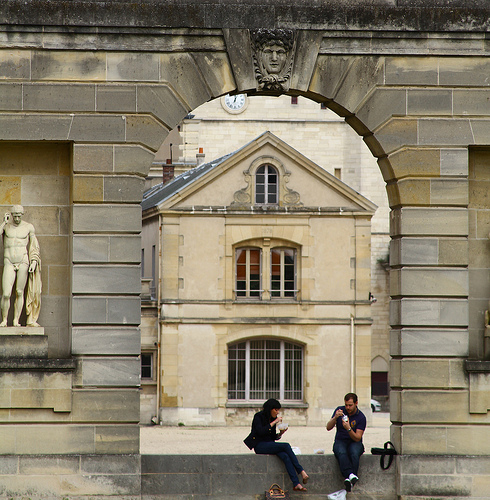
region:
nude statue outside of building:
[2, 200, 42, 330]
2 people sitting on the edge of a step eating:
[243, 377, 371, 493]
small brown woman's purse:
[260, 482, 291, 498]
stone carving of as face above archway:
[240, 25, 302, 90]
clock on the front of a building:
[218, 89, 253, 112]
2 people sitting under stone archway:
[94, 67, 421, 484]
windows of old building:
[221, 228, 314, 302]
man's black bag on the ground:
[370, 442, 400, 468]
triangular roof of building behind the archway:
[125, 129, 394, 220]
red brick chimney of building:
[160, 141, 180, 185]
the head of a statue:
[11, 199, 26, 224]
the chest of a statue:
[4, 222, 32, 241]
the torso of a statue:
[0, 233, 30, 261]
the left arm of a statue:
[25, 223, 43, 273]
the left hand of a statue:
[25, 254, 40, 277]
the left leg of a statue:
[16, 275, 38, 326]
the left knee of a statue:
[12, 282, 27, 294]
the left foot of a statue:
[14, 318, 28, 332]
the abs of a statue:
[5, 230, 20, 253]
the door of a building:
[225, 342, 311, 409]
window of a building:
[249, 157, 272, 176]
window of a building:
[270, 156, 284, 185]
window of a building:
[249, 171, 267, 190]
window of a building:
[241, 189, 273, 214]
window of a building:
[268, 187, 287, 213]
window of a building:
[237, 240, 267, 268]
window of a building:
[269, 245, 302, 266]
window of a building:
[228, 264, 261, 280]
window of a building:
[273, 266, 298, 280]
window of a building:
[234, 279, 260, 294]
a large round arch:
[144, 69, 384, 455]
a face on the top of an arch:
[246, 24, 307, 85]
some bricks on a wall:
[116, 76, 165, 134]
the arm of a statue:
[25, 231, 71, 306]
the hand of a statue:
[14, 254, 47, 279]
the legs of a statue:
[0, 269, 28, 320]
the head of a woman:
[246, 392, 285, 421]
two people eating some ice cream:
[256, 394, 369, 468]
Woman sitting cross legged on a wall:
[240, 395, 312, 493]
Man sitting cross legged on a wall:
[324, 390, 368, 492]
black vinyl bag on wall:
[369, 437, 399, 471]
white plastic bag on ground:
[323, 486, 349, 498]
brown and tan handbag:
[259, 480, 291, 498]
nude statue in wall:
[0, 199, 47, 334]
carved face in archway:
[255, 28, 294, 84]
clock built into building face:
[220, 93, 250, 115]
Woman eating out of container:
[238, 390, 317, 495]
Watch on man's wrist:
[346, 426, 352, 431]